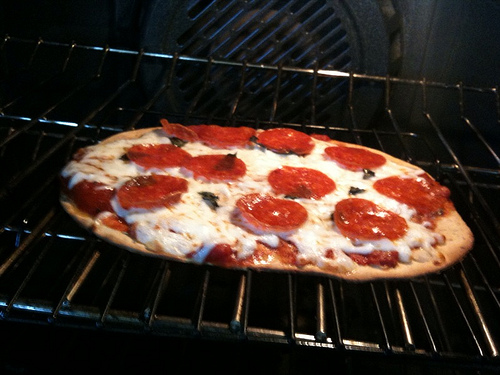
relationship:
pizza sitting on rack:
[55, 107, 479, 284] [0, 32, 496, 366]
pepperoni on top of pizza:
[236, 190, 308, 232] [55, 107, 479, 284]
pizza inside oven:
[55, 107, 479, 284] [1, 1, 499, 374]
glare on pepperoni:
[365, 208, 389, 220] [334, 196, 406, 239]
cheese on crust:
[64, 125, 456, 271] [58, 120, 475, 282]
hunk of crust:
[435, 209, 475, 264] [58, 120, 475, 282]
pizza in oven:
[55, 107, 479, 284] [1, 1, 499, 374]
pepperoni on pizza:
[123, 115, 449, 241] [55, 107, 479, 284]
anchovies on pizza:
[215, 150, 237, 169] [55, 107, 479, 284]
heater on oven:
[139, 2, 390, 149] [1, 1, 499, 374]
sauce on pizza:
[70, 177, 116, 221] [55, 107, 479, 284]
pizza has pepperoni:
[55, 107, 479, 284] [123, 115, 449, 241]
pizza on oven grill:
[55, 107, 479, 284] [0, 32, 496, 366]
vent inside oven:
[139, 2, 390, 149] [1, 1, 499, 374]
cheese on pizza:
[64, 125, 456, 271] [55, 107, 479, 284]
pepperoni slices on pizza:
[123, 115, 449, 241] [55, 107, 479, 284]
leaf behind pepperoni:
[284, 181, 312, 202] [267, 165, 335, 198]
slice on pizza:
[125, 143, 194, 170] [55, 107, 479, 284]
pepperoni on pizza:
[269, 161, 342, 196] [55, 107, 479, 284]